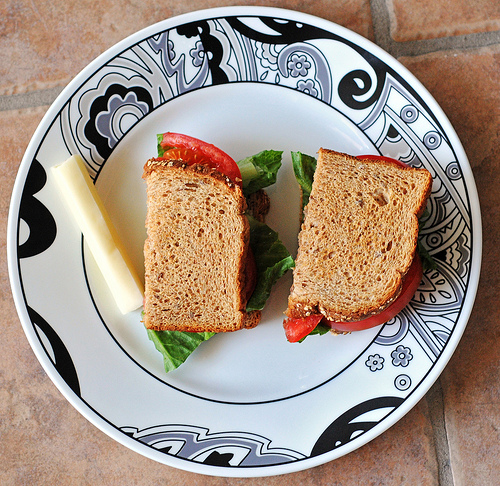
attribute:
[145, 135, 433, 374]
pieces of sandwich — cut in two, cut in half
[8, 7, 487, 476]
plate — round, disc-like, in use, black, white, blue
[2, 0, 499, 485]
surface — tiled, red, copper colored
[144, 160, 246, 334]
bread — brown, wheat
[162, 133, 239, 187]
slice of tomato — ripe, red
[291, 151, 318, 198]
piece of vegetable — green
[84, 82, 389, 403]
portion of plate — white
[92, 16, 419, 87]
design — blue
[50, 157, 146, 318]
cheese — long, white, small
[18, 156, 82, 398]
decorations — black on the plate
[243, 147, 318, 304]
lettuce — sliced